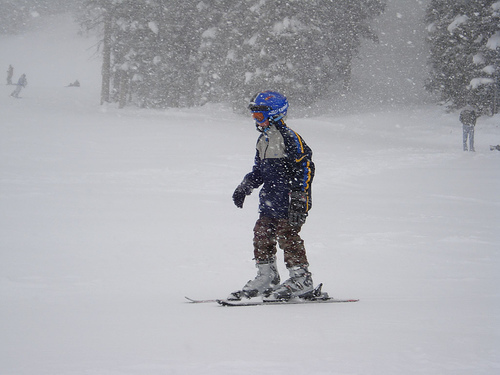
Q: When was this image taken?
A: During the day.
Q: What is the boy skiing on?
A: Snow.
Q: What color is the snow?
A: White.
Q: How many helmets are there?
A: One.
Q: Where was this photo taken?
A: On a ski slope.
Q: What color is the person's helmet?
A: Blue.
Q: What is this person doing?
A: Skiing.